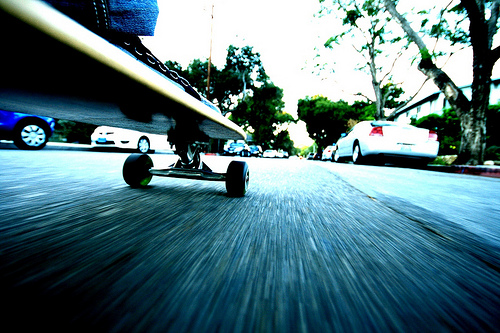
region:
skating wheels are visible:
[104, 141, 315, 219]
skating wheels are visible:
[32, 100, 279, 202]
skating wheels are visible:
[101, 112, 276, 254]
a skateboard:
[7, 0, 252, 210]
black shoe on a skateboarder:
[69, 5, 230, 110]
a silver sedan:
[338, 115, 440, 162]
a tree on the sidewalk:
[393, 0, 489, 162]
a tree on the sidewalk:
[324, 0, 441, 123]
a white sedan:
[91, 120, 198, 153]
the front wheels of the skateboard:
[118, 145, 249, 204]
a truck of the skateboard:
[147, 121, 222, 186]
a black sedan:
[223, 142, 252, 157]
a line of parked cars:
[58, 118, 297, 158]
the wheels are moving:
[72, 135, 297, 225]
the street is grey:
[49, 162, 390, 298]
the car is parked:
[327, 107, 467, 198]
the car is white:
[319, 115, 461, 180]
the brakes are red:
[347, 117, 452, 154]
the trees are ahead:
[249, 87, 364, 145]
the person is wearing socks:
[83, 5, 205, 103]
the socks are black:
[106, 30, 200, 110]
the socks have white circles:
[115, 29, 192, 92]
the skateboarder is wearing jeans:
[44, 0, 174, 52]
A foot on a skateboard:
[2, 8, 272, 209]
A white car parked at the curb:
[323, 102, 450, 184]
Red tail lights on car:
[363, 117, 445, 145]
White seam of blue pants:
[86, 4, 113, 31]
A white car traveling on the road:
[78, 122, 222, 167]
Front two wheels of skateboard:
[116, 146, 261, 218]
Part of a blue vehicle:
[6, 111, 65, 169]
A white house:
[376, 88, 494, 175]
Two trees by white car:
[333, 3, 498, 134]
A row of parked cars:
[223, 127, 291, 169]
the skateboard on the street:
[5, 2, 254, 197]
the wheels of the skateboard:
[113, 149, 250, 200]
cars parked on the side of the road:
[316, 117, 442, 166]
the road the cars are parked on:
[7, 153, 498, 325]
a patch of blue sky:
[172, 5, 334, 82]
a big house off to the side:
[403, 50, 494, 118]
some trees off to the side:
[178, 50, 363, 140]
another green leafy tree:
[304, 86, 364, 137]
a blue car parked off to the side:
[1, 106, 58, 148]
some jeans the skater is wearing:
[79, 2, 162, 34]